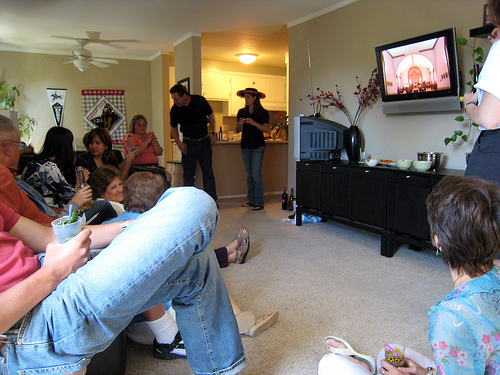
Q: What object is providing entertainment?
A: The television.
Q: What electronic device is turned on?
A: The television.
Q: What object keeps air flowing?
A: The ceiling fan.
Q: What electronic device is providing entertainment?
A: The television.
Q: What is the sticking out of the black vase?
A: A plant.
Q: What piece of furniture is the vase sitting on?
A: The black television stand.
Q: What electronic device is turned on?
A: The television on the wall.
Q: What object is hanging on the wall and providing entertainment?
A: The flat screen television.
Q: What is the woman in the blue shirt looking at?
A: The TV.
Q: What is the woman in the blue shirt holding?
A: A cup.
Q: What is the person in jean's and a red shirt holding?
A: A cup.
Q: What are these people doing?
A: Hanging out and watching TV.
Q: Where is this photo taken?
A: In a living room.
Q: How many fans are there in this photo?
A: One.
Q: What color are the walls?
A: Brown and white.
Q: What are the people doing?
A: Watching tv.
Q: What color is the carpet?
A: White.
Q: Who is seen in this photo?
A: Men and women.